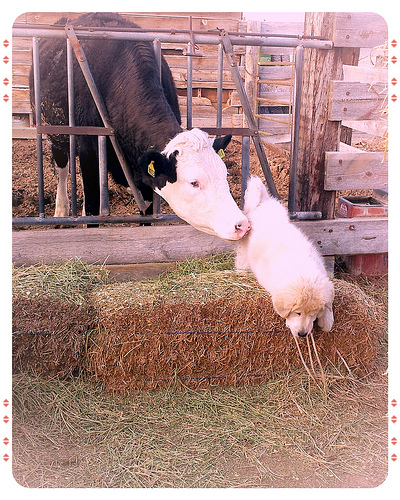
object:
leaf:
[256, 437, 289, 447]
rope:
[294, 352, 333, 386]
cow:
[25, 9, 251, 245]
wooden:
[291, 13, 347, 224]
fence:
[11, 5, 386, 263]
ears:
[137, 148, 181, 183]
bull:
[29, 13, 250, 242]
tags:
[216, 147, 224, 158]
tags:
[146, 160, 156, 178]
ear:
[212, 133, 232, 151]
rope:
[135, 328, 329, 338]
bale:
[91, 274, 378, 393]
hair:
[161, 126, 214, 159]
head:
[146, 121, 251, 244]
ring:
[235, 222, 253, 234]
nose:
[225, 206, 254, 243]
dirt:
[263, 451, 351, 480]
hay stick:
[278, 326, 356, 405]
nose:
[298, 327, 310, 338]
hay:
[13, 266, 394, 487]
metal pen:
[6, 21, 331, 228]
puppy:
[232, 167, 335, 360]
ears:
[270, 288, 294, 318]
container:
[330, 190, 387, 280]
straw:
[14, 374, 388, 487]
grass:
[13, 375, 387, 486]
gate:
[13, 25, 334, 241]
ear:
[136, 150, 167, 176]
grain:
[7, 259, 385, 488]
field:
[19, 19, 386, 476]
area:
[225, 449, 398, 486]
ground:
[20, 269, 384, 486]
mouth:
[287, 320, 315, 339]